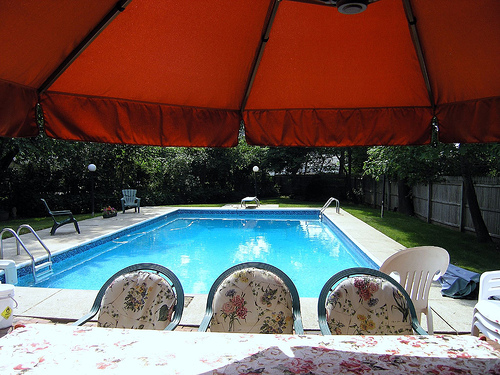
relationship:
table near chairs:
[4, 315, 495, 371] [75, 257, 434, 334]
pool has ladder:
[29, 200, 414, 304] [1, 217, 67, 285]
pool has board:
[29, 200, 414, 304] [232, 194, 269, 208]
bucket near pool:
[0, 285, 21, 324] [29, 200, 414, 304]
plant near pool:
[98, 206, 126, 221] [29, 200, 414, 304]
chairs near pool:
[75, 257, 434, 334] [29, 200, 414, 304]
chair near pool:
[364, 221, 500, 342] [29, 200, 414, 304]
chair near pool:
[35, 185, 152, 236] [29, 200, 414, 304]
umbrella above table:
[0, 2, 499, 152] [4, 315, 495, 371]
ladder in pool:
[1, 217, 67, 285] [29, 200, 414, 304]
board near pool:
[232, 194, 269, 208] [29, 200, 414, 304]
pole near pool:
[84, 162, 111, 218] [29, 200, 414, 304]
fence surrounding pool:
[148, 171, 495, 234] [29, 200, 414, 304]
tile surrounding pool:
[179, 208, 321, 215] [29, 200, 414, 304]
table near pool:
[4, 315, 495, 371] [29, 200, 414, 304]